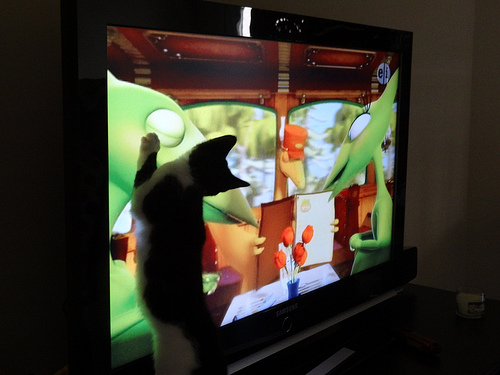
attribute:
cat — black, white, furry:
[132, 113, 252, 372]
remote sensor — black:
[271, 11, 309, 42]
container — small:
[456, 282, 487, 322]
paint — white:
[3, 2, 500, 372]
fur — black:
[134, 129, 249, 374]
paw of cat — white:
[139, 131, 163, 155]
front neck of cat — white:
[162, 152, 193, 190]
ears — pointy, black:
[213, 129, 249, 199]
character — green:
[326, 62, 398, 275]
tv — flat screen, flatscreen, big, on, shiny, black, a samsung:
[58, 0, 420, 374]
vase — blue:
[286, 276, 302, 300]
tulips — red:
[270, 222, 315, 281]